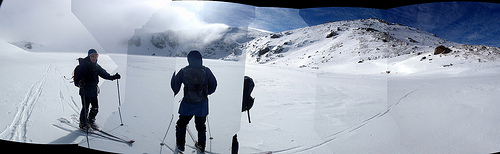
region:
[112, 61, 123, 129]
Man holding ski sticks.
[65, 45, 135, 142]
Man standing on his skis.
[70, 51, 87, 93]
Man carrying a backpack on his back.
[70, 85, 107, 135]
Man wearing dark pants.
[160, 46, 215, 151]
Man standing on his skis.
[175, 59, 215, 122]
Man wearing a blue snow jacket.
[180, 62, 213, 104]
Man carrying a blue backpack on his back.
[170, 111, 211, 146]
Man wearing black pants.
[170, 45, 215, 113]
Man wearing blue jacket with hood on his head.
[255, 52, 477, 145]
Ground covered of snow.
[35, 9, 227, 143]
Man skiing in the snow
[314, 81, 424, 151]
Tracks in the snow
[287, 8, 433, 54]
Snow on top of the hill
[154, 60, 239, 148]
Man wearing a winter coat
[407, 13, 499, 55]
The sky is blue with some clouds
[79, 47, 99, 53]
Man wearing a beanie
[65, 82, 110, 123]
Man holding ski poles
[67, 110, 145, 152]
Man standing on skis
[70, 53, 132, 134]
Man wearing a coat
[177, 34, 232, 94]
Man has hood on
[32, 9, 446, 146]
This is on a mountain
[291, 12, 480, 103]
There is lots of snow on the mountain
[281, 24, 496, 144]
The snow is white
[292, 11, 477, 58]
The sky is clear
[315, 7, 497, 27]
The sky is very bright blue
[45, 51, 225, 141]
These men are skiing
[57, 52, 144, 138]
This man has ski poles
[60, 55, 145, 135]
The man is wearing black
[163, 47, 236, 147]
This man has his back to the camera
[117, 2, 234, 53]
The sun is shining here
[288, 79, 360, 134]
snow on the ground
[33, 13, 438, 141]
two different photos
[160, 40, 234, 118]
person with back towards the camera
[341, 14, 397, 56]
mountain in the distance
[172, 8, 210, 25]
light in the background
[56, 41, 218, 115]
two different people in the photo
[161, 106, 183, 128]
ski pole in the man's hand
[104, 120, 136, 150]
skis on the ground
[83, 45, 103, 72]
head of the man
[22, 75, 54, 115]
tracks in the snow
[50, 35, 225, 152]
Two skiiers facing each other.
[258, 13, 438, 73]
A snow covered hill.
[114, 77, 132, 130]
A ski propelling stick.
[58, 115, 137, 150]
A set of white skiis.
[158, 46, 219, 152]
A skiier with his back to the camera.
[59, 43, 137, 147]
A skiier facing east.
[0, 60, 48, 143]
Ski tracks in the snow.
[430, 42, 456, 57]
A bare black rock.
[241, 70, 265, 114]
A blue back pack.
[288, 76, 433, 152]
A longer set of tracks in the snow.